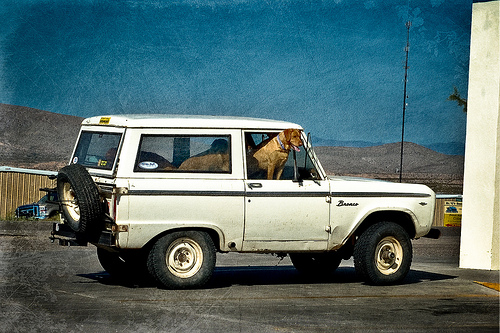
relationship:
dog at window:
[249, 130, 303, 181] [244, 130, 323, 182]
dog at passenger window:
[249, 130, 303, 181] [244, 130, 323, 182]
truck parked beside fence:
[12, 192, 61, 219] [0, 169, 58, 219]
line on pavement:
[121, 290, 492, 304] [1, 229, 496, 333]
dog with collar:
[249, 130, 303, 181] [273, 134, 288, 153]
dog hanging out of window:
[249, 130, 303, 181] [244, 130, 323, 182]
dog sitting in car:
[249, 130, 303, 181] [56, 113, 441, 293]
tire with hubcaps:
[357, 219, 414, 286] [375, 238, 405, 276]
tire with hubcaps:
[145, 232, 218, 291] [165, 238, 203, 278]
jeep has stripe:
[56, 113, 441, 293] [118, 190, 435, 201]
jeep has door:
[56, 113, 441, 293] [248, 181, 263, 191]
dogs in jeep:
[104, 114, 304, 185] [56, 113, 441, 293]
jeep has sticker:
[56, 113, 441, 293] [97, 115, 113, 125]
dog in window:
[249, 130, 303, 181] [244, 130, 323, 182]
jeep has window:
[37, 109, 441, 293] [244, 130, 323, 182]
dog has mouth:
[249, 130, 303, 181] [291, 143, 306, 153]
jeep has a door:
[37, 109, 441, 293] [248, 181, 263, 191]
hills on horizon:
[0, 99, 464, 195] [1, 1, 464, 183]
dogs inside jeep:
[104, 114, 304, 185] [37, 109, 441, 293]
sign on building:
[444, 197, 464, 216] [432, 186, 462, 225]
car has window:
[56, 113, 441, 293] [132, 135, 233, 175]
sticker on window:
[136, 159, 159, 171] [132, 135, 233, 175]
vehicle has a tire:
[56, 113, 441, 293] [357, 219, 414, 286]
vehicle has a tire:
[56, 113, 441, 293] [145, 232, 218, 291]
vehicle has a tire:
[56, 113, 441, 293] [55, 165, 104, 243]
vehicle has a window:
[56, 113, 441, 293] [244, 130, 323, 182]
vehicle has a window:
[56, 113, 441, 293] [132, 135, 233, 175]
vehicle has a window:
[56, 113, 441, 293] [67, 124, 122, 174]